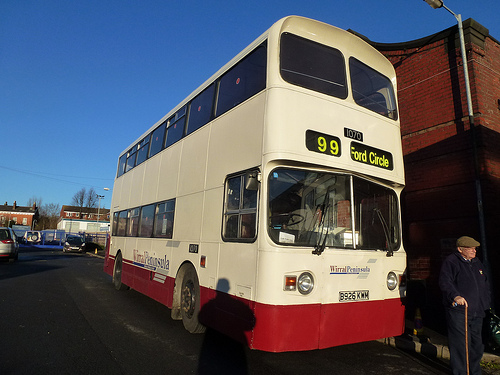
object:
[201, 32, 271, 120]
windows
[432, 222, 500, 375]
man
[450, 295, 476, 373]
cane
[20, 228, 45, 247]
cars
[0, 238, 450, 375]
road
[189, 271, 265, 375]
shadow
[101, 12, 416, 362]
bus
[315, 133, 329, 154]
number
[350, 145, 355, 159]
letter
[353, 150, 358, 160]
letter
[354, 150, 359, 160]
letter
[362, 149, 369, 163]
letter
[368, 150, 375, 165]
letter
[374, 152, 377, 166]
letter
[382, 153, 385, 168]
letter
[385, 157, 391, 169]
letter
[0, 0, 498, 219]
sky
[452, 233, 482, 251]
hat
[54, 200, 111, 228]
houses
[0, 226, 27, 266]
car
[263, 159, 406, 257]
windshield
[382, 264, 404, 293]
headlights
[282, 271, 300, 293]
blinker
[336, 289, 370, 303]
license plate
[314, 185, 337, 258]
wipers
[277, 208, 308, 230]
steering wheel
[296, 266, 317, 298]
headlights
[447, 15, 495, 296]
pole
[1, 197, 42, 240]
buildings